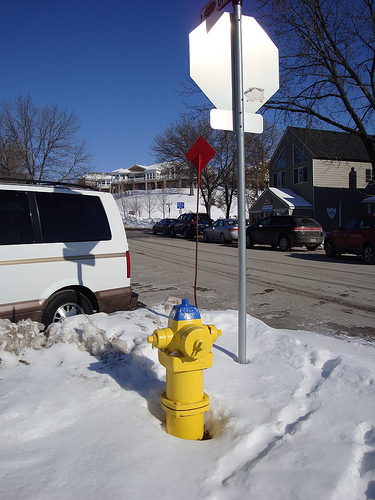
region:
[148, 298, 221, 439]
a blue and yellow hydrant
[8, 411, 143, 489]
snow on the pavement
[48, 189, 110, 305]
the shadow of the traffic sign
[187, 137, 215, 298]
a red traffic sign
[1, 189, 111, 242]
a tinted van window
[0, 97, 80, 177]
branches of a dry tree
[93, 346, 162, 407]
the shadow of the hydrant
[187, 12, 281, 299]
the rear view of a traffic sign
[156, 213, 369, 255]
several parked cars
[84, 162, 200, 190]
some houses in the distance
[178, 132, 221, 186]
Red sign on a pole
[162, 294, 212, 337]
blue top of yellow fire hydrant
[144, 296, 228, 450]
Yellow and blue fire hydrant in snow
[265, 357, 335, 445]
Foot step in snow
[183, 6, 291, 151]
Back of stop sign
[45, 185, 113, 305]
Shadow of stop sign on car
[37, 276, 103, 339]
Rear right wheel of parked van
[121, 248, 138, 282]
Rear red tail light of van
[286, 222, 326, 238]
red tail light of dark vehicle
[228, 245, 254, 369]
metal pole in snow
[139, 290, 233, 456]
fire hydrant in the snow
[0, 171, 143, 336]
vehicle parked next to snow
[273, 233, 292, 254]
rear wheel on a vehicle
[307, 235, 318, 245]
rear licence plate on a vehicle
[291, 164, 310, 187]
window on a building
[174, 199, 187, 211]
blue and white sign on a pole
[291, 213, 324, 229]
rear window on a vehicle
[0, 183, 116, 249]
side windows on a vehicle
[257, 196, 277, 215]
sign on a building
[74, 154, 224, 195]
buildings on a hill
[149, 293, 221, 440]
Yellow and blue fireplug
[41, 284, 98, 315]
Black rear truck tire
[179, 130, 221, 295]
Part of traffic street sign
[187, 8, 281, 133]
Back of traffic street sign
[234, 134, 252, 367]
Metal pole for traffic sign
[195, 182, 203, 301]
Metal pole for traffic sign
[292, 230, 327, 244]
Back bumper of parked car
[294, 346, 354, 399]
Dark footpring in white snow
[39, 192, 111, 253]
Back window of white vehicle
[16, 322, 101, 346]
Shoveled dirty snow on side of drive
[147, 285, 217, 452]
fire hydrant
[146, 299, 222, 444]
blue and yellow fire hydrant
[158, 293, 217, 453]
yellow and blue fire hydrant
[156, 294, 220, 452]
yellow and blue hydrant in white snow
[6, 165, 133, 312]
white van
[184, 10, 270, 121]
back of stop sign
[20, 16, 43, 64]
white clouds in blue sky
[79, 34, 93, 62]
white clouds in blue sky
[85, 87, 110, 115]
white clouds in blue sky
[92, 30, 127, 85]
white clouds in blue sky